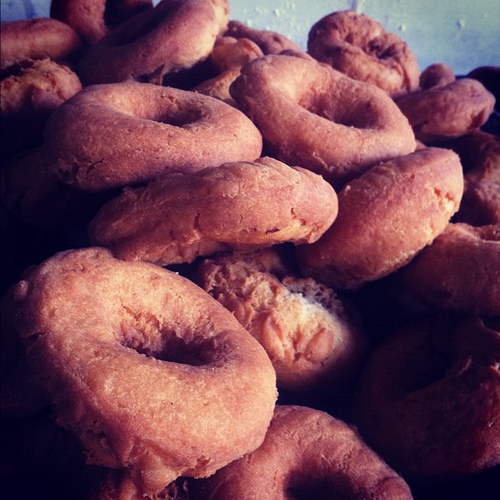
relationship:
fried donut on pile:
[39, 246, 275, 471] [58, 42, 461, 489]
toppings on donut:
[271, 261, 352, 338] [59, 73, 254, 175]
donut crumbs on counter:
[233, 2, 315, 49] [247, 4, 478, 80]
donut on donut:
[59, 73, 254, 175] [103, 162, 349, 252]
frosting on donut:
[250, 244, 359, 349] [59, 73, 254, 175]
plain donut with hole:
[230, 50, 417, 184] [120, 313, 234, 373]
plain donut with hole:
[230, 50, 417, 184] [276, 458, 371, 496]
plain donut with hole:
[230, 50, 417, 184] [263, 249, 356, 323]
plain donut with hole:
[230, 50, 417, 184] [112, 90, 212, 135]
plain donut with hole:
[230, 50, 417, 184] [291, 79, 382, 138]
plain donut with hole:
[230, 50, 417, 184] [344, 31, 394, 65]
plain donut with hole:
[230, 50, 417, 184] [474, 225, 496, 242]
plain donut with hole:
[230, 50, 417, 184] [3, 52, 34, 75]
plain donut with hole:
[230, 50, 417, 184] [104, 3, 137, 43]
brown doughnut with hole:
[86, 4, 239, 84] [119, 312, 220, 377]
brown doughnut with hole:
[86, 4, 239, 84] [291, 79, 382, 138]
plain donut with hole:
[230, 50, 417, 184] [120, 319, 225, 376]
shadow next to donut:
[326, 259, 448, 362] [4, 405, 94, 495]